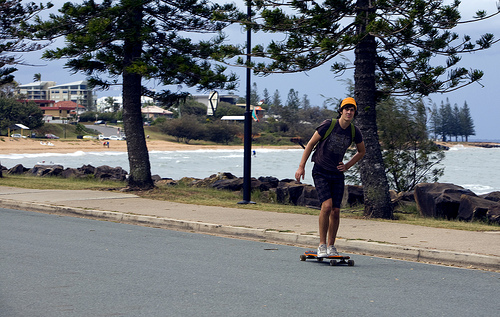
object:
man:
[294, 97, 367, 257]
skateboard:
[300, 250, 355, 266]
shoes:
[318, 244, 328, 257]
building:
[46, 80, 99, 114]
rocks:
[33, 165, 60, 176]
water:
[64, 155, 128, 168]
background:
[168, 155, 202, 179]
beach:
[27, 145, 72, 153]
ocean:
[151, 143, 304, 179]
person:
[118, 126, 121, 137]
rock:
[458, 194, 499, 222]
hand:
[337, 161, 348, 172]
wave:
[12, 151, 31, 158]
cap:
[339, 97, 357, 108]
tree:
[19, 0, 248, 191]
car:
[10, 132, 23, 139]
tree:
[232, 0, 500, 220]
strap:
[322, 119, 336, 141]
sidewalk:
[0, 183, 500, 259]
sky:
[291, 74, 339, 100]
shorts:
[312, 164, 347, 208]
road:
[0, 208, 500, 294]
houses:
[14, 80, 56, 100]